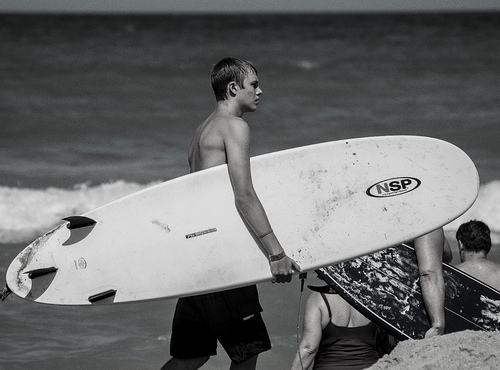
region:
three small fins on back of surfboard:
[5, 201, 123, 351]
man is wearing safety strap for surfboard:
[259, 245, 314, 305]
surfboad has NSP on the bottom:
[342, 146, 447, 224]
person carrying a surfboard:
[302, 239, 499, 344]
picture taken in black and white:
[59, 41, 448, 364]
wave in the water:
[16, 168, 127, 270]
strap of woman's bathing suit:
[288, 282, 367, 335]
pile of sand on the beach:
[334, 307, 497, 365]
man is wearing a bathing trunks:
[131, 268, 316, 368]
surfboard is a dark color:
[379, 246, 497, 351]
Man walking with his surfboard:
[16, 62, 481, 354]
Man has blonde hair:
[206, 58, 255, 105]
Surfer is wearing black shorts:
[161, 298, 271, 368]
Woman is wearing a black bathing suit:
[300, 289, 388, 369]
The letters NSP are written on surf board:
[358, 167, 426, 211]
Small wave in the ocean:
[7, 157, 72, 228]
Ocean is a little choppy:
[333, 84, 493, 129]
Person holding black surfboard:
[354, 248, 499, 333]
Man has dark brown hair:
[450, 222, 499, 267]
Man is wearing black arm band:
[245, 220, 282, 247]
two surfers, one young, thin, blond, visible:
[149, 49, 498, 369]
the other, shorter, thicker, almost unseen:
[396, 191, 458, 354]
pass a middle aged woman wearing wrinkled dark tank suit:
[268, 277, 408, 369]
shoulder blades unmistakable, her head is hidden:
[305, 283, 381, 331]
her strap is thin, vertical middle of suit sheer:
[308, 296, 380, 369]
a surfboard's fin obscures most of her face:
[301, 278, 345, 299]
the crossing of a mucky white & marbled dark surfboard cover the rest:
[267, 136, 429, 343]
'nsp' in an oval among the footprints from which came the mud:
[359, 168, 424, 205]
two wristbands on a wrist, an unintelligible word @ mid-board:
[180, 221, 288, 263]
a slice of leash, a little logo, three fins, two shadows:
[0, 196, 127, 315]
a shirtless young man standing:
[166, 56, 273, 367]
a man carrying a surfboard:
[7, 50, 481, 368]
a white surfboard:
[6, 129, 484, 311]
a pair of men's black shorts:
[167, 285, 274, 360]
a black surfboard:
[292, 220, 497, 340]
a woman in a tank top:
[291, 284, 383, 369]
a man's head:
[454, 219, 492, 261]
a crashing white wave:
[0, 184, 132, 240]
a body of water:
[3, 12, 493, 368]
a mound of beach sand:
[372, 329, 497, 369]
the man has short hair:
[206, 47, 259, 106]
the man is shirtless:
[153, 51, 302, 368]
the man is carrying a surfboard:
[3, 53, 480, 368]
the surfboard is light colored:
[0, 129, 484, 327]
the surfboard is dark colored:
[303, 237, 498, 348]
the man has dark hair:
[456, 220, 495, 258]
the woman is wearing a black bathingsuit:
[311, 287, 386, 369]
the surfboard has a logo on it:
[361, 173, 421, 198]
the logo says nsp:
[365, 173, 420, 198]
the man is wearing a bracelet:
[258, 224, 289, 265]